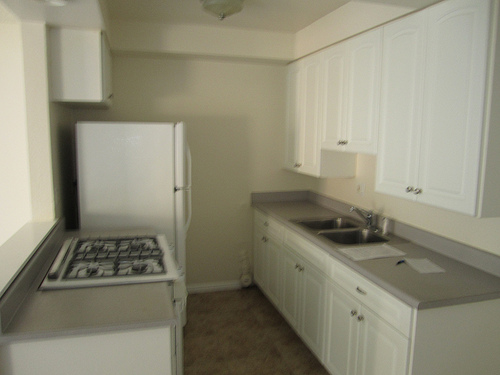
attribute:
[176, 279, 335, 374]
floor — tiled, beige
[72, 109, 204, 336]
refrigerator — white 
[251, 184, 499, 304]
kitchen counter — gray 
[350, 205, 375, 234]
faucet — silver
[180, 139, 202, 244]
handles — white 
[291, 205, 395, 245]
sink — chrome, double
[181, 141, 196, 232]
handle — White 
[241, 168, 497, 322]
counter — grey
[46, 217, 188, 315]
stove — white 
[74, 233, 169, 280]
grates — black 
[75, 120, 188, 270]
freezer — White 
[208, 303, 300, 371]
floor — tan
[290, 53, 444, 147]
white cabinets — white 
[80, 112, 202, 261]
efridgerator — white 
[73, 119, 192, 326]
fridge — White 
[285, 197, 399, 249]
sink — stainless 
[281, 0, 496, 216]
cabinets — White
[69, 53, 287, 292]
wall — beige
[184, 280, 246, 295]
molding — white 